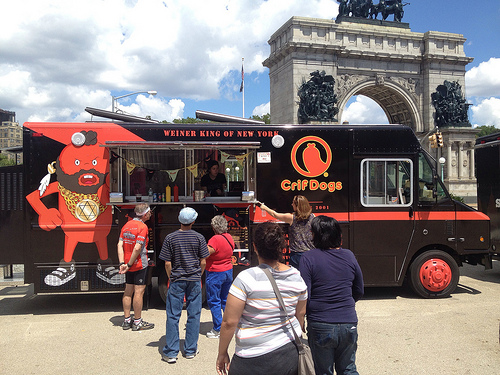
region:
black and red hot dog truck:
[30, 87, 465, 311]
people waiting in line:
[100, 177, 353, 370]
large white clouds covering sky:
[22, 8, 253, 111]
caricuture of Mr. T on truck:
[37, 120, 133, 290]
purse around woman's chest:
[235, 233, 324, 370]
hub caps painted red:
[417, 255, 452, 293]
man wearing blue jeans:
[162, 262, 213, 360]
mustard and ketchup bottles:
[164, 179, 183, 203]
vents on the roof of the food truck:
[83, 105, 275, 126]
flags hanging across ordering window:
[97, 143, 271, 190]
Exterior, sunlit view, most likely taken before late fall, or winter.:
[0, 0, 496, 370]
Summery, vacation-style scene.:
[5, 1, 492, 372]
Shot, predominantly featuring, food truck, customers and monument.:
[10, 7, 498, 372]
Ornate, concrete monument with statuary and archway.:
[271, 0, 491, 215]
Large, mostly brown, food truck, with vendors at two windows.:
[23, 117, 485, 298]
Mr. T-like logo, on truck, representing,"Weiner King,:
[30, 136, 125, 286]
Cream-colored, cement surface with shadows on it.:
[6, 298, 224, 369]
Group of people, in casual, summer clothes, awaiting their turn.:
[125, 185, 363, 368]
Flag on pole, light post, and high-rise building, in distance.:
[0, 70, 272, 157]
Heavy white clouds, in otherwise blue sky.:
[49, 5, 246, 103]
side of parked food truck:
[18, 118, 473, 315]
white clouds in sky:
[2, 2, 329, 114]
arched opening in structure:
[337, 75, 431, 126]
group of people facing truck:
[115, 197, 354, 368]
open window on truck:
[182, 146, 260, 202]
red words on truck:
[154, 127, 283, 142]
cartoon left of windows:
[31, 132, 118, 287]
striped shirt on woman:
[225, 262, 309, 359]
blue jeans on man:
[158, 276, 204, 361]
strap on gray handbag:
[264, 268, 316, 373]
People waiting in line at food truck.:
[116, 197, 367, 372]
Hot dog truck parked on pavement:
[0, 119, 493, 311]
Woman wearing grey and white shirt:
[213, 220, 309, 374]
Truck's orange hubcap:
[417, 256, 454, 293]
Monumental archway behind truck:
[263, 0, 480, 208]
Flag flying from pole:
[232, 59, 252, 108]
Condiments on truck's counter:
[133, 182, 210, 203]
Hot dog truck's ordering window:
[105, 147, 244, 199]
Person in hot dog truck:
[198, 157, 226, 193]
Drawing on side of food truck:
[24, 128, 120, 288]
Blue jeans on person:
[157, 275, 203, 355]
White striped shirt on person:
[223, 263, 313, 360]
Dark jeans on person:
[298, 313, 362, 373]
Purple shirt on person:
[290, 247, 376, 334]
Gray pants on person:
[222, 337, 303, 373]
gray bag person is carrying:
[255, 259, 321, 374]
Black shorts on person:
[121, 266, 153, 289]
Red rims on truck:
[417, 256, 454, 295]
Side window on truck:
[355, 148, 417, 213]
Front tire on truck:
[398, 235, 469, 306]